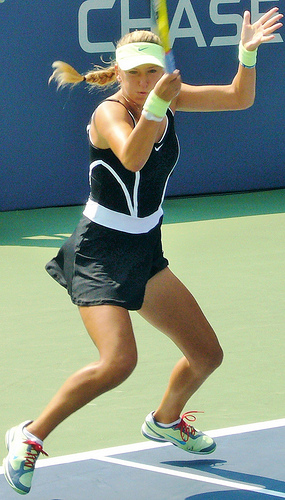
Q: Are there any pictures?
A: No, there are no pictures.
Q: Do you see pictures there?
A: No, there are no pictures.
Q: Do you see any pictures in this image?
A: No, there are no pictures.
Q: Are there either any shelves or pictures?
A: No, there are no pictures or shelves.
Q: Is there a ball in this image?
A: No, there are no balls.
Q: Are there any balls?
A: No, there are no balls.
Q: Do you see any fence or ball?
A: No, there are no balls or fences.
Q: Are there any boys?
A: No, there are no boys.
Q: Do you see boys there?
A: No, there are no boys.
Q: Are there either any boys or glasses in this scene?
A: No, there are no boys or glasses.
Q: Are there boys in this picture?
A: No, there are no boys.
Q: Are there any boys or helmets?
A: No, there are no boys or helmets.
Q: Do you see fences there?
A: No, there are no fences.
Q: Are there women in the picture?
A: Yes, there is a woman.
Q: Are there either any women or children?
A: Yes, there is a woman.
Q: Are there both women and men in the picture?
A: No, there is a woman but no men.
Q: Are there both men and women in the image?
A: No, there is a woman but no men.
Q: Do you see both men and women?
A: No, there is a woman but no men.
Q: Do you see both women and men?
A: No, there is a woman but no men.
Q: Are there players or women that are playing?
A: Yes, the woman is playing.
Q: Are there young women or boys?
A: Yes, there is a young woman.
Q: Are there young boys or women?
A: Yes, there is a young woman.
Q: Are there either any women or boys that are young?
A: Yes, the woman is young.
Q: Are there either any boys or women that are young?
A: Yes, the woman is young.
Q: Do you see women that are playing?
A: Yes, there is a woman that is playing.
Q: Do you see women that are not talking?
A: Yes, there is a woman that is playing .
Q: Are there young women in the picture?
A: Yes, there is a young woman.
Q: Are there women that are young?
A: Yes, there is a woman that is young.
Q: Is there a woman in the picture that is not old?
A: Yes, there is an young woman.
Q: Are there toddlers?
A: No, there are no toddlers.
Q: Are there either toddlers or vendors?
A: No, there are no toddlers or vendors.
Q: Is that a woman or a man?
A: That is a woman.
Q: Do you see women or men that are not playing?
A: No, there is a woman but she is playing.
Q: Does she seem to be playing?
A: Yes, the woman is playing.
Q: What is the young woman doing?
A: The woman is playing.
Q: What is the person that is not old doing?
A: The woman is playing.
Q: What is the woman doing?
A: The woman is playing.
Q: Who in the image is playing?
A: The woman is playing.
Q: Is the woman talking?
A: No, the woman is playing.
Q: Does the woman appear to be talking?
A: No, the woman is playing.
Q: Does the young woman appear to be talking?
A: No, the woman is playing.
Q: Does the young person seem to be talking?
A: No, the woman is playing.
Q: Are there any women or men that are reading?
A: No, there is a woman but she is playing.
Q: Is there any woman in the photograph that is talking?
A: No, there is a woman but she is playing.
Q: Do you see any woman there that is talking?
A: No, there is a woman but she is playing.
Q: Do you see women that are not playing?
A: No, there is a woman but she is playing.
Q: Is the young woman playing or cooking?
A: The woman is playing.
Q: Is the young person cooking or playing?
A: The woman is playing.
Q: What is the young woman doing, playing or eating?
A: The woman is playing.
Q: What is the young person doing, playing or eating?
A: The woman is playing.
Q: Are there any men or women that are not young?
A: No, there is a woman but she is young.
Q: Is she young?
A: Yes, the woman is young.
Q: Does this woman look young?
A: Yes, the woman is young.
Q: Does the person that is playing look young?
A: Yes, the woman is young.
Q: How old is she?
A: The woman is young.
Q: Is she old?
A: No, the woman is young.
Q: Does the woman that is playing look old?
A: No, the woman is young.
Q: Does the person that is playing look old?
A: No, the woman is young.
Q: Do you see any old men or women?
A: No, there is a woman but she is young.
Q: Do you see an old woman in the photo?
A: No, there is a woman but she is young.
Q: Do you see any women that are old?
A: No, there is a woman but she is young.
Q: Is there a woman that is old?
A: No, there is a woman but she is young.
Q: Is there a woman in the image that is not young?
A: No, there is a woman but she is young.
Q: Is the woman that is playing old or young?
A: The woman is young.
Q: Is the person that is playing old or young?
A: The woman is young.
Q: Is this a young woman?
A: Yes, this is a young woman.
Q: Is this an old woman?
A: No, this is a young woman.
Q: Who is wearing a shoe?
A: The woman is wearing a shoe.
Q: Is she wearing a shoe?
A: Yes, the woman is wearing a shoe.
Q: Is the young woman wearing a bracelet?
A: No, the woman is wearing a shoe.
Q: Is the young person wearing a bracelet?
A: No, the woman is wearing a shoe.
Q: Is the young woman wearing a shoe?
A: Yes, the woman is wearing a shoe.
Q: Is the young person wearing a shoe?
A: Yes, the woman is wearing a shoe.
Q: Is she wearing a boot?
A: No, the woman is wearing a shoe.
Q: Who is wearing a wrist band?
A: The woman is wearing a wrist band.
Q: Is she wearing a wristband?
A: Yes, the woman is wearing a wristband.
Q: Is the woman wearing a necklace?
A: No, the woman is wearing a wristband.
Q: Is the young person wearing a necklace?
A: No, the woman is wearing a wristband.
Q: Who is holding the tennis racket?
A: The woman is holding the tennis racket.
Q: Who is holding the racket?
A: The woman is holding the tennis racket.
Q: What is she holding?
A: The woman is holding the racket.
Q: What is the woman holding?
A: The woman is holding the racket.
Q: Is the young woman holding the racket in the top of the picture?
A: Yes, the woman is holding the racket.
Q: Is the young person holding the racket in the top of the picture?
A: Yes, the woman is holding the racket.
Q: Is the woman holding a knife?
A: No, the woman is holding the racket.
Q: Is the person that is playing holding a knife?
A: No, the woman is holding the racket.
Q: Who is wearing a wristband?
A: The woman is wearing a wristband.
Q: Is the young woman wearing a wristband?
A: Yes, the woman is wearing a wristband.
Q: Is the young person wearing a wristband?
A: Yes, the woman is wearing a wristband.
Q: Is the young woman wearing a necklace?
A: No, the woman is wearing a wristband.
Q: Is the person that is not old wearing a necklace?
A: No, the woman is wearing a wristband.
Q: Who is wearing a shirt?
A: The woman is wearing a shirt.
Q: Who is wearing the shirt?
A: The woman is wearing a shirt.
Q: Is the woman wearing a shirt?
A: Yes, the woman is wearing a shirt.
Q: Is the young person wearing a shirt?
A: Yes, the woman is wearing a shirt.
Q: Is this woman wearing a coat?
A: No, the woman is wearing a shirt.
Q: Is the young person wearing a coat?
A: No, the woman is wearing a shirt.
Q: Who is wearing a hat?
A: The woman is wearing a hat.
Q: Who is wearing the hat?
A: The woman is wearing a hat.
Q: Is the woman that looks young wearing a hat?
A: Yes, the woman is wearing a hat.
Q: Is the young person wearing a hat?
A: Yes, the woman is wearing a hat.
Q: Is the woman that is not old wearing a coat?
A: No, the woman is wearing a hat.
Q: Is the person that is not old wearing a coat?
A: No, the woman is wearing a hat.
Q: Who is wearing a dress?
A: The woman is wearing a dress.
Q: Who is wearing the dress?
A: The woman is wearing a dress.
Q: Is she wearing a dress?
A: Yes, the woman is wearing a dress.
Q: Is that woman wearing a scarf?
A: No, the woman is wearing a dress.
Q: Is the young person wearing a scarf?
A: No, the woman is wearing a dress.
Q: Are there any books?
A: No, there are no books.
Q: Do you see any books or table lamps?
A: No, there are no books or table lamps.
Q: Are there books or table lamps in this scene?
A: No, there are no books or table lamps.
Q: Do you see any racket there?
A: Yes, there is a racket.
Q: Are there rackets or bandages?
A: Yes, there is a racket.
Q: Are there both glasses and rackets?
A: No, there is a racket but no glasses.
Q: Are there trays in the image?
A: No, there are no trays.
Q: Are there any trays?
A: No, there are no trays.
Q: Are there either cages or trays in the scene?
A: No, there are no trays or cages.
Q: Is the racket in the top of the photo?
A: Yes, the racket is in the top of the image.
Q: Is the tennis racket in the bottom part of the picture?
A: No, the tennis racket is in the top of the image.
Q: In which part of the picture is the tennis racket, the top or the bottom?
A: The tennis racket is in the top of the image.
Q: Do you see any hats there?
A: Yes, there is a hat.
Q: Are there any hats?
A: Yes, there is a hat.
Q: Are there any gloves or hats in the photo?
A: Yes, there is a hat.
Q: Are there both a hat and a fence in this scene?
A: No, there is a hat but no fences.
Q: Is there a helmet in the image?
A: No, there are no helmets.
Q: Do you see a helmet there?
A: No, there are no helmets.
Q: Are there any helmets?
A: No, there are no helmets.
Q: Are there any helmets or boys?
A: No, there are no helmets or boys.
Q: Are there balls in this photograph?
A: No, there are no balls.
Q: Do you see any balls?
A: No, there are no balls.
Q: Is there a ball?
A: No, there are no balls.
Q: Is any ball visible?
A: No, there are no balls.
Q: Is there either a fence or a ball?
A: No, there are no balls or fences.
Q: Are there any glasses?
A: No, there are no glasses.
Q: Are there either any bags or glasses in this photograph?
A: No, there are no glasses or bags.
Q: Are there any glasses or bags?
A: No, there are no glasses or bags.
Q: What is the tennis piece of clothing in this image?
A: The clothing item is a dress.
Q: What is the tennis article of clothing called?
A: The clothing item is a dress.